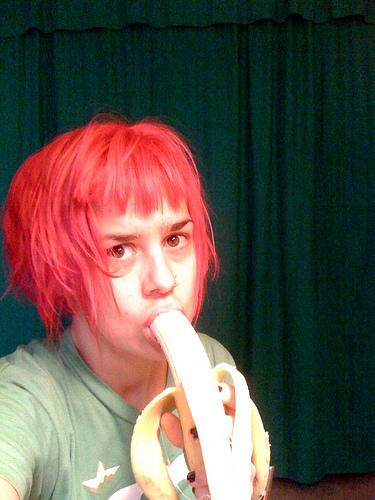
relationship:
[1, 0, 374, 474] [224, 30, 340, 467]
drapes have pleats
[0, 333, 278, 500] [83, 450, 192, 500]
shirt has logo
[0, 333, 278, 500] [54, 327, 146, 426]
shirt has collar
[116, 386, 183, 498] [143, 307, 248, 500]
peel of banana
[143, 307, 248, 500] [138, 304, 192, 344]
banana in mouth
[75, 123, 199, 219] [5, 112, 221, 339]
bangs on head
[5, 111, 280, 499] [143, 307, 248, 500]
woman eating banana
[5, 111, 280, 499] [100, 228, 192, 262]
woman has brown eyes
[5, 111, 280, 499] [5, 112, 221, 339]
woman wears wig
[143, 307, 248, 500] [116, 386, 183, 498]
banana has peel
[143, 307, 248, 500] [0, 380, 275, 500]
banana on left hand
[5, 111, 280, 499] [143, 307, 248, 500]
woman eats banana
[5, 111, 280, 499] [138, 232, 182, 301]
woman seen nose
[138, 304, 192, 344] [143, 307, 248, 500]
lips around banana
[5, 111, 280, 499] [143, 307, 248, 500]
boy eating banana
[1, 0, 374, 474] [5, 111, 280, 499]
curtain behind person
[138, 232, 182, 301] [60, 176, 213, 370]
nose in face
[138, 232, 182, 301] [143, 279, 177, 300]
nose seen nostril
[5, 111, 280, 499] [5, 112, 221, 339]
woman with red hair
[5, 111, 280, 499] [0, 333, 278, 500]
woman has green shirt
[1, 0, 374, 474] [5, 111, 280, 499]
curtain behind woman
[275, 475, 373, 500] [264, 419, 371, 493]
wood covering floor